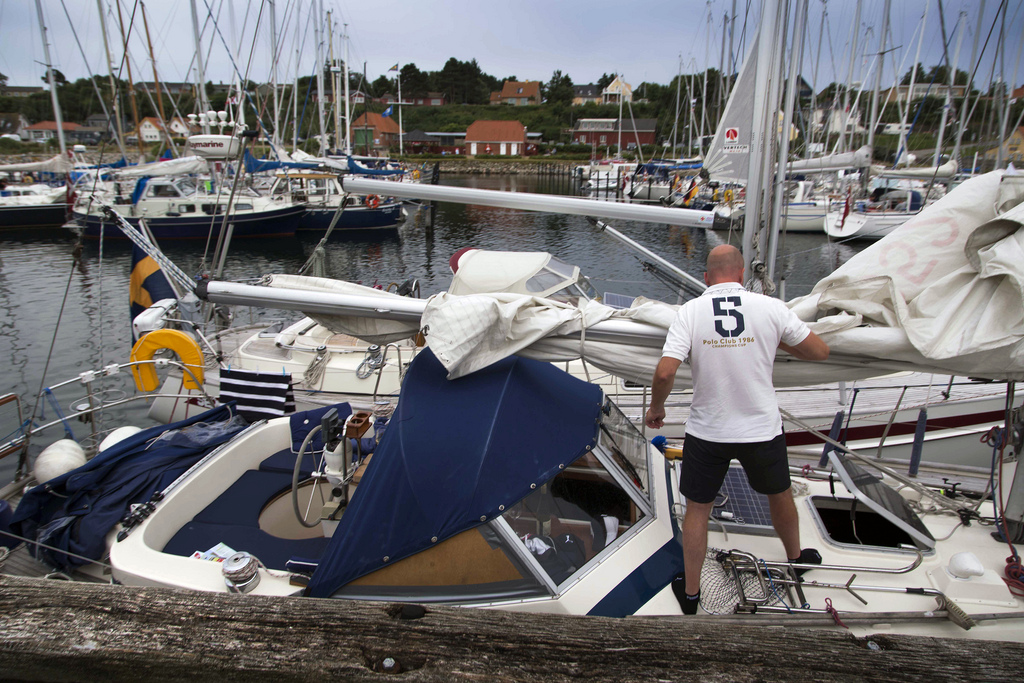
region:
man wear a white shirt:
[651, 268, 836, 424]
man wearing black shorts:
[664, 427, 804, 511]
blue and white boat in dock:
[62, 168, 307, 255]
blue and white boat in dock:
[60, 316, 1016, 674]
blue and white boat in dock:
[294, 170, 412, 231]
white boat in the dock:
[805, 183, 914, 247]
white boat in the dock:
[771, 165, 842, 223]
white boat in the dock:
[629, 174, 681, 194]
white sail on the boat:
[844, 165, 1019, 358]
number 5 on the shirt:
[697, 291, 777, 345]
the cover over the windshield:
[294, 339, 615, 596]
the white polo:
[656, 287, 811, 443]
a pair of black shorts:
[675, 429, 796, 502]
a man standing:
[644, 240, 835, 623]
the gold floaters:
[126, 249, 204, 396]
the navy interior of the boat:
[0, 393, 356, 570]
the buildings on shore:
[2, 69, 1006, 162]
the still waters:
[0, 177, 833, 473]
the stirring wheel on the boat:
[288, 411, 349, 536]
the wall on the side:
[3, 573, 1022, 679]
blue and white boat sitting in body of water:
[65, 181, 304, 248]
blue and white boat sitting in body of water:
[271, 170, 405, 232]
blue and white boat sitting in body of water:
[0, 179, 73, 230]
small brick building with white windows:
[464, 123, 531, 156]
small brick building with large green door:
[352, 116, 410, 154]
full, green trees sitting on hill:
[440, 60, 483, 103]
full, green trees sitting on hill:
[401, 60, 428, 95]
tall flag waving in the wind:
[390, 62, 406, 161]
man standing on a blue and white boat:
[650, 241, 831, 618]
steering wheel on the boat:
[267, 413, 372, 533]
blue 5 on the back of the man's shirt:
[700, 284, 749, 357]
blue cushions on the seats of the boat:
[146, 412, 343, 592]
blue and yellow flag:
[96, 214, 243, 386]